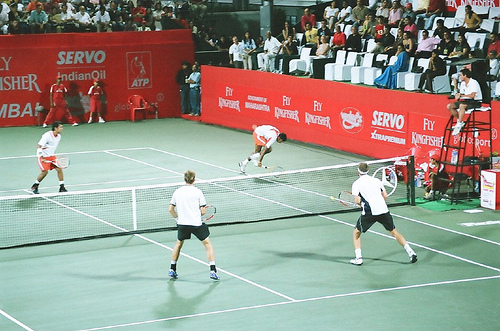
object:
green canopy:
[449, 57, 481, 64]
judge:
[446, 67, 481, 134]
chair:
[433, 56, 493, 206]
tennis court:
[3, 123, 498, 329]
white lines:
[76, 272, 499, 329]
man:
[32, 123, 69, 194]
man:
[350, 160, 419, 264]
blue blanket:
[373, 54, 413, 86]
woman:
[363, 39, 408, 96]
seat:
[429, 59, 486, 196]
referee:
[439, 67, 481, 139]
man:
[237, 124, 286, 175]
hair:
[279, 133, 288, 142]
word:
[55, 46, 67, 66]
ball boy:
[40, 75, 78, 129]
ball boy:
[86, 77, 106, 126]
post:
[407, 155, 416, 206]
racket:
[255, 163, 293, 179]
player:
[238, 122, 286, 174]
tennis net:
[2, 142, 412, 248]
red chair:
[127, 92, 160, 124]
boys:
[36, 71, 117, 128]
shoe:
[450, 119, 464, 136]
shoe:
[407, 251, 418, 265]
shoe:
[346, 258, 363, 264]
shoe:
[207, 271, 219, 280]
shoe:
[166, 269, 178, 278]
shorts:
[174, 222, 211, 241]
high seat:
[422, 93, 483, 207]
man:
[166, 169, 245, 297]